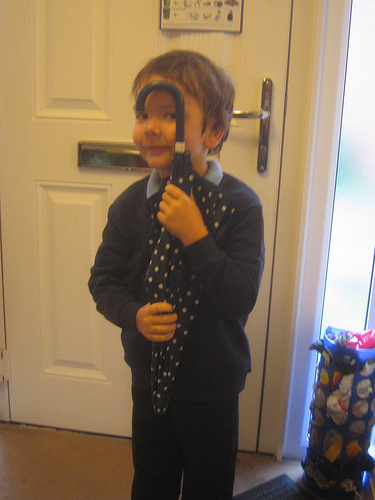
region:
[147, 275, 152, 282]
white polkadot next to white polkadot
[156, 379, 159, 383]
white polkadot next to white polkadot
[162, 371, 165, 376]
white polkadot next to white polkadot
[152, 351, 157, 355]
white polkadot next to white polkadot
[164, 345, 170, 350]
white polkadot next to white polkadot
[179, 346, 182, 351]
white polkadot next to white polkadot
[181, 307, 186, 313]
white polkadot next to white polkadot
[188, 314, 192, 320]
white polkadot next to white polkadot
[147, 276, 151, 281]
white polkadot next to white polkadot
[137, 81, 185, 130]
black tip to umbrella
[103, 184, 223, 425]
black umbrella in hands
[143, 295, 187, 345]
hand on top of umbrella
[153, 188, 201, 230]
hand grasping umbrella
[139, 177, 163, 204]
blue collar to shirt on kid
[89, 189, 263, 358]
dark blue sweatshirt on kid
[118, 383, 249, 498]
black pants on kid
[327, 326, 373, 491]
blue sock rack in back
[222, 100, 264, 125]
part of a gray door handle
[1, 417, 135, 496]
part of a floor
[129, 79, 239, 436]
a blue and white umbrella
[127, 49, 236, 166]
a boy's short cut hair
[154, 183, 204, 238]
the hand of a boy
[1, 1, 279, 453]
part of a white door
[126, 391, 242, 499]
part of a boy's pants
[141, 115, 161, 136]
the nose of a boy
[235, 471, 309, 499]
part of a black rug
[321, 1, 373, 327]
a long window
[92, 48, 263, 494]
a boy holding an umbrella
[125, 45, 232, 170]
a boy with a smirk on his face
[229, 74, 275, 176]
a silver door handle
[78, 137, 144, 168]
a silver mail drop slot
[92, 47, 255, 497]
boy wearing dark blue clothes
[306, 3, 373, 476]
light coming in a window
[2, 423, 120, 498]
beige colored floor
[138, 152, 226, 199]
light blue shirt collar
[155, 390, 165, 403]
white dot on umbrella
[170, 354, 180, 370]
white dot on umbrella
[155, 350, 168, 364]
white dot on umbrella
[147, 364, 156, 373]
white dot on umbrella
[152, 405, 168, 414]
white dot on umbrella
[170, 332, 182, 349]
white dot on umbrella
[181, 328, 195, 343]
white dot on umbrella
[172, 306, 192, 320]
white dot on umbrella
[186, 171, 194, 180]
White polka dot on the umbrella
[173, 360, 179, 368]
White polka dot on the umbrella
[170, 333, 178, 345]
White polka dot on the umbrella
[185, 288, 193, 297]
White polka dot on the umbrella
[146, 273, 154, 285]
White polka dot on the umbrella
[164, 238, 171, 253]
White polka dot on the umbrella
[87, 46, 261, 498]
Young child holding an umbrella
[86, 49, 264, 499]
Young boy holding an umbrella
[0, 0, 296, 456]
White door behind the young boy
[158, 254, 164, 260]
White dot on the umbrella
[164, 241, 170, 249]
White dot on the umbrella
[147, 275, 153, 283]
White dot on the umbrella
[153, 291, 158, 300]
White dot on the umbrella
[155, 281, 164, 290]
White dot on the umbrella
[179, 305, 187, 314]
White dot on the umbrella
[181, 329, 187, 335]
White dot on the umbrella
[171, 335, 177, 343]
White dot on the umbrella